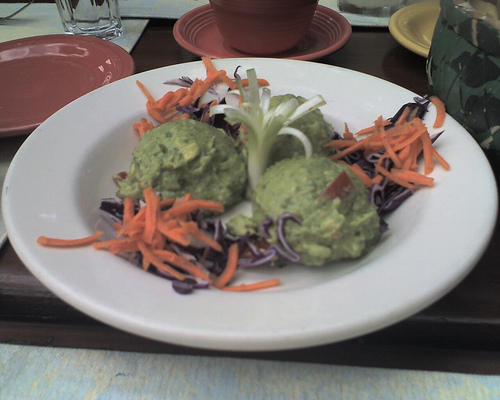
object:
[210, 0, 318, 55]
cup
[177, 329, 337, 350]
edge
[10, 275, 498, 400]
table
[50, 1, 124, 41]
glass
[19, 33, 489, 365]
plate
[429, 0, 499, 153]
pot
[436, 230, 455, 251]
ground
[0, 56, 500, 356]
dish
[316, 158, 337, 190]
ground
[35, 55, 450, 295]
food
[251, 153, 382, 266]
ball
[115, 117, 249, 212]
ball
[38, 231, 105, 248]
veggie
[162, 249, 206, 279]
veggie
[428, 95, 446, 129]
veggie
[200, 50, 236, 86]
veggie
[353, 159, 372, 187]
veggie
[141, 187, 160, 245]
carrots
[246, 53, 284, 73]
ground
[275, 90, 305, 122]
ground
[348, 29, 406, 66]
table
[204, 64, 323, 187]
fruit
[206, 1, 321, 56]
bowl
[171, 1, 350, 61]
saucer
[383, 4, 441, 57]
plate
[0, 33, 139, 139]
plate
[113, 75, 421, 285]
ingredients